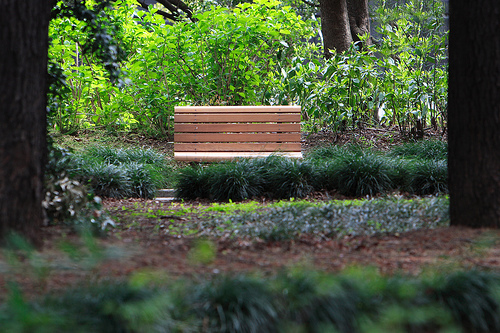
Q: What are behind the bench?
A: Bushes.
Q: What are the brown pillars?
A: Trees.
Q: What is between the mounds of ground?
A: Stream.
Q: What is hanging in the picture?
A: Swing.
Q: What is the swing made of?
A: Wood.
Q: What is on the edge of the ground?
A: Grass.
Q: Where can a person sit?
A: Bench.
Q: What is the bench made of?
A: Wood.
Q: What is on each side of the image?
A: Tree.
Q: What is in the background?
A: Plants.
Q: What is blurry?
A: Bottom of image.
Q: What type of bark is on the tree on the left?
A: Rough bark.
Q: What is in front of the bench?
A: Grass.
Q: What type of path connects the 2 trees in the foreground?
A: Dirt path.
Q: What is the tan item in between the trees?
A: Bench.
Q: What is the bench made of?
A: Wood.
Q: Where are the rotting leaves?
A: On the ground.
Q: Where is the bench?
A: Among the trees.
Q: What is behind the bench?
A: Bushes.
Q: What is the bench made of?
A: Wood.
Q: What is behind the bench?
A: Green bushes.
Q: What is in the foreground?
A: Groundcover.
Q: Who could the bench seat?
A: Two people.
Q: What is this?
A: A bench.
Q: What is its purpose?
A: To allow somewhere to sit.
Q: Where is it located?
A: By the walkway.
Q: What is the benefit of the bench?
A: To allow rest.